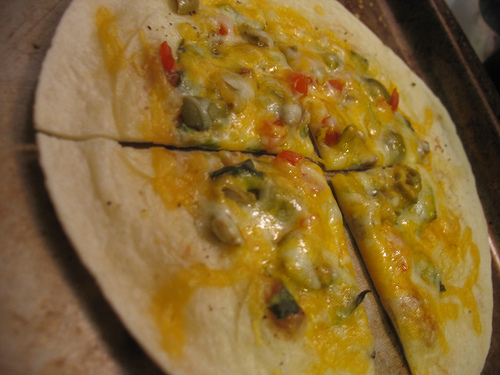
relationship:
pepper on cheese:
[159, 41, 182, 71] [33, 0, 493, 375]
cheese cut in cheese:
[33, 0, 493, 375] [33, 0, 493, 375]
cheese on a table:
[33, 0, 493, 375] [1, 5, 482, 364]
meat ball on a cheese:
[278, 229, 323, 290] [33, 0, 493, 375]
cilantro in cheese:
[208, 159, 266, 183] [92, 1, 482, 369]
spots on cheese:
[146, 8, 175, 38] [33, 0, 493, 375]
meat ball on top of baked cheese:
[181, 94, 229, 129] [33, 0, 493, 375]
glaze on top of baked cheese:
[93, 6, 481, 369] [33, 0, 493, 375]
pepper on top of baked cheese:
[160, 41, 175, 71] [33, 0, 493, 375]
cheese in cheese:
[33, 0, 493, 375] [33, 0, 493, 375]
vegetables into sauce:
[152, 40, 435, 321] [92, 3, 482, 370]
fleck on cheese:
[96, 185, 126, 215] [33, 0, 493, 375]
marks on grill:
[5, 275, 113, 372] [3, 0, 498, 375]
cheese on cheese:
[169, 11, 451, 329] [33, 0, 493, 375]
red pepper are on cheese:
[291, 72, 313, 95] [33, 0, 493, 375]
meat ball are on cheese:
[181, 94, 229, 129] [33, 0, 493, 375]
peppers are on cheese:
[275, 147, 300, 162] [33, 0, 493, 375]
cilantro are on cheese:
[211, 158, 264, 179] [33, 0, 493, 375]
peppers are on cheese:
[362, 71, 392, 100] [33, 0, 493, 375]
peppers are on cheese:
[388, 89, 397, 111] [33, 0, 493, 375]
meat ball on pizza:
[175, 81, 233, 140] [32, 3, 320, 163]